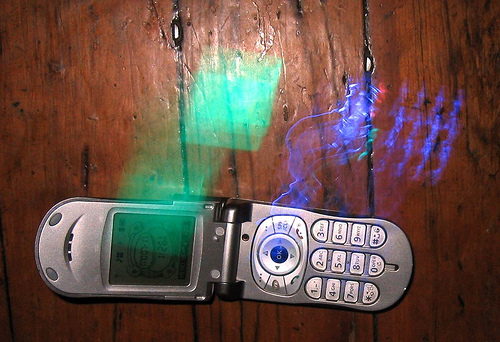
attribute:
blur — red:
[369, 81, 389, 122]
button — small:
[307, 246, 329, 272]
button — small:
[341, 277, 361, 304]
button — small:
[346, 249, 366, 275]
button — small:
[350, 220, 368, 249]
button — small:
[369, 223, 388, 249]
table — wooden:
[3, 2, 483, 336]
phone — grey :
[26, 169, 429, 321]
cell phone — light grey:
[38, 182, 422, 312]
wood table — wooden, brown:
[6, 2, 500, 336]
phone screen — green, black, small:
[102, 209, 202, 297]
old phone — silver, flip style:
[20, 195, 424, 318]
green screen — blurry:
[102, 213, 197, 281]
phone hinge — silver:
[220, 205, 241, 286]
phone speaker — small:
[384, 249, 408, 281]